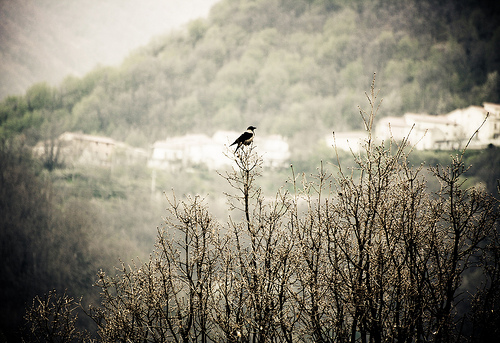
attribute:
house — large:
[34, 134, 149, 180]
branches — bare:
[336, 120, 451, 335]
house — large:
[49, 127, 133, 157]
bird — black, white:
[228, 121, 259, 151]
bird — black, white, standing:
[226, 122, 258, 150]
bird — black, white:
[230, 124, 258, 157]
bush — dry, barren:
[188, 240, 483, 332]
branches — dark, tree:
[321, 108, 478, 341]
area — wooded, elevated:
[123, 15, 430, 133]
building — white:
[324, 97, 497, 177]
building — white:
[150, 125, 285, 163]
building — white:
[30, 126, 150, 183]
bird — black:
[224, 121, 261, 153]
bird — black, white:
[226, 119, 264, 157]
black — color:
[228, 130, 256, 152]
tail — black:
[232, 140, 240, 153]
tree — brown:
[322, 142, 491, 339]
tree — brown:
[221, 187, 353, 339]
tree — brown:
[106, 204, 252, 340]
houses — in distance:
[319, 100, 498, 154]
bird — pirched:
[230, 123, 259, 153]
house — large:
[345, 111, 485, 156]